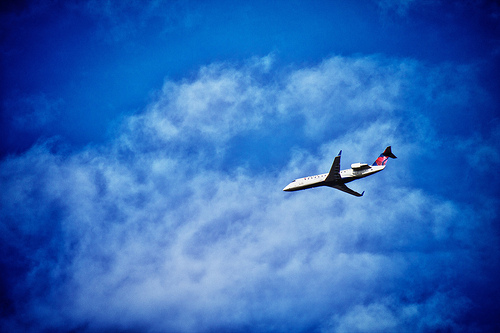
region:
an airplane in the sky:
[241, 143, 496, 282]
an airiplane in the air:
[247, 57, 486, 317]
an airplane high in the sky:
[242, 89, 427, 280]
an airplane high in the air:
[262, 85, 489, 312]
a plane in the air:
[229, 78, 349, 242]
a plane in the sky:
[271, 75, 479, 299]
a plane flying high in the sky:
[299, 84, 424, 234]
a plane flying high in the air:
[194, 64, 479, 329]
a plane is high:
[221, 47, 429, 314]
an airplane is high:
[207, 88, 496, 285]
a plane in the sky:
[280, 137, 401, 205]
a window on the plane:
[301, 175, 308, 185]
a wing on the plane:
[321, 142, 352, 185]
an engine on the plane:
[348, 159, 372, 173]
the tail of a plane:
[368, 136, 400, 176]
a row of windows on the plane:
[298, 171, 329, 183]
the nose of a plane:
[281, 180, 292, 192]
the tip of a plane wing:
[330, 142, 348, 158]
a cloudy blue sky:
[0, 0, 497, 331]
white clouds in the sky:
[0, 35, 418, 325]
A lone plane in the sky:
[273, 133, 393, 215]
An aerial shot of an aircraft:
[17, 19, 488, 329]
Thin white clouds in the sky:
[51, 154, 276, 311]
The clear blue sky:
[53, 50, 134, 95]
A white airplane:
[290, 155, 395, 182]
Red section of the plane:
[366, 150, 386, 166]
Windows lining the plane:
[298, 175, 329, 182]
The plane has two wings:
[311, 148, 357, 198]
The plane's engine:
[352, 160, 364, 175]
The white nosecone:
[282, 176, 301, 196]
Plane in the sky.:
[212, 105, 461, 228]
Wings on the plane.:
[295, 137, 442, 192]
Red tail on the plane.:
[317, 123, 447, 186]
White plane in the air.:
[223, 47, 482, 262]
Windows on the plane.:
[251, 143, 408, 231]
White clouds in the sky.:
[115, 81, 388, 230]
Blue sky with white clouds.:
[10, 56, 421, 233]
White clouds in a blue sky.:
[138, 47, 432, 239]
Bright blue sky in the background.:
[173, 120, 435, 290]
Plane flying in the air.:
[269, 112, 341, 178]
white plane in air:
[307, 138, 412, 218]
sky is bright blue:
[60, 23, 287, 221]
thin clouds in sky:
[80, 48, 296, 315]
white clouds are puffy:
[65, 150, 264, 284]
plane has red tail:
[345, 133, 401, 194]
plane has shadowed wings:
[325, 152, 385, 209]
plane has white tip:
[260, 155, 303, 202]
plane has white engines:
[345, 141, 365, 188]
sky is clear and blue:
[27, 9, 147, 157]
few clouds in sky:
[110, 63, 212, 230]